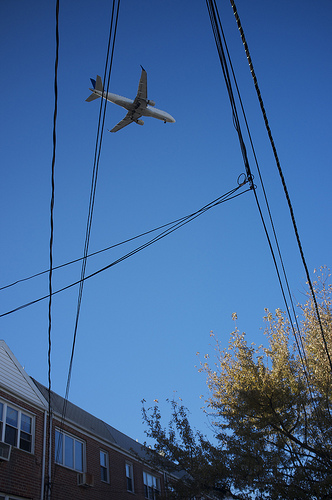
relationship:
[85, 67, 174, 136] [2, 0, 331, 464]
airplane flying in sky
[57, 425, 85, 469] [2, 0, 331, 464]
window reflects sky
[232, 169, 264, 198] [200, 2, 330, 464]
wiring loops around wires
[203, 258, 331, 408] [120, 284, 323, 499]
sunlight on tree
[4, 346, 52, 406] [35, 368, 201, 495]
siding on roof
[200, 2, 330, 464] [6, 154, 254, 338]
wires attached to wires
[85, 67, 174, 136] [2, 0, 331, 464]
airplane in sky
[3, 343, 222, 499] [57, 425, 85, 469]
building has window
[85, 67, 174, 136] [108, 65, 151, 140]
airplane has wings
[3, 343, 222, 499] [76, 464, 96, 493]
building has a air conditioning uni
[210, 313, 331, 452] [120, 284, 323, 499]
branch of tree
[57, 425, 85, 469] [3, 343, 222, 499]
window on building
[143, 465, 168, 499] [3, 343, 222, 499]
window on building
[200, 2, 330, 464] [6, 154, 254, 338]
wires with wires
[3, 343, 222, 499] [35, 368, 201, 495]
building with a roof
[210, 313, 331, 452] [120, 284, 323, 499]
branch on tree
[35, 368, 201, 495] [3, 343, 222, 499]
roof of building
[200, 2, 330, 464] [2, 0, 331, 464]
wires in sky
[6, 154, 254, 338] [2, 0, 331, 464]
wires in sky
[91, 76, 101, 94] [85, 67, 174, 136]
tail fin on an airplane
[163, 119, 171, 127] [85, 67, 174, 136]
front wheel on airplane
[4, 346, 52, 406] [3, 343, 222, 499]
siding on building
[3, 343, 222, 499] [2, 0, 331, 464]
building below sky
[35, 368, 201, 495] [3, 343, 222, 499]
roof to building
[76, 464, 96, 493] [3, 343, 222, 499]
air conditioning uni on building